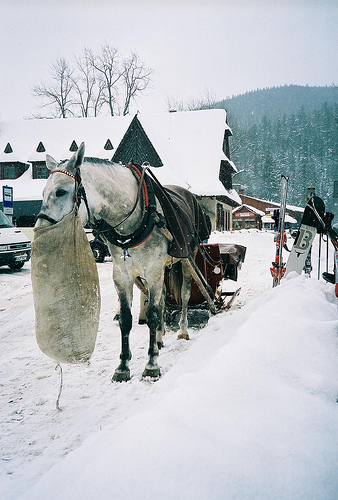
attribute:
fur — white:
[96, 174, 130, 201]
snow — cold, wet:
[174, 297, 327, 414]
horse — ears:
[17, 106, 302, 361]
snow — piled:
[18, 276, 336, 499]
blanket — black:
[125, 170, 226, 271]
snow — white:
[1, 107, 336, 498]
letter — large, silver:
[296, 228, 311, 253]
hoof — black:
[142, 358, 163, 387]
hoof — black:
[108, 361, 133, 383]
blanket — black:
[150, 180, 210, 260]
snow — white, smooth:
[224, 436, 314, 498]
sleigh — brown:
[181, 258, 237, 314]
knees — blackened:
[109, 300, 166, 337]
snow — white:
[154, 372, 268, 460]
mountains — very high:
[206, 83, 334, 129]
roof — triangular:
[0, 110, 169, 186]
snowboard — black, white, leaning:
[283, 195, 325, 277]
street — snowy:
[1, 218, 336, 499]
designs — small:
[125, 132, 147, 163]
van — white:
[4, 213, 16, 300]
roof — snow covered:
[14, 102, 261, 192]